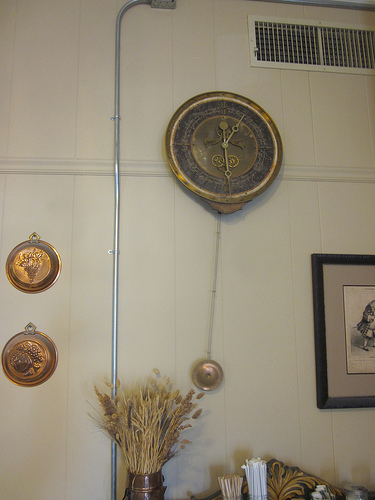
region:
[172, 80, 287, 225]
Clock on wall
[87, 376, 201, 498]
Cluster of wheat in container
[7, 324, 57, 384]
Bronze circle on wall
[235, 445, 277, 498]
White straws are clustered together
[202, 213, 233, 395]
Pendulum on clock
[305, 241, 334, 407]
Black border of picture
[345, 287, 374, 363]
Portrait of Alice in Wonderland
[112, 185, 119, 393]
Pole on wall is silver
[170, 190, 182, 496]
Cleft between two boards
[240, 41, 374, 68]
White vent in wall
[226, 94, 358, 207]
a clock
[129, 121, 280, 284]
a clock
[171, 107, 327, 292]
a clock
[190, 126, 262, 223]
a clock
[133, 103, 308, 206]
a clock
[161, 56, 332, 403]
a clock on the wall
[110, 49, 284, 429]
an old clock on the wall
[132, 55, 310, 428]
an antique clock on the wall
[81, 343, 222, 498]
a vase of plants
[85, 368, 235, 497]
plants in a vase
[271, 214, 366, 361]
a picture on the wall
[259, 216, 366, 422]
a framed picture on the wall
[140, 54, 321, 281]
a clock with gold arms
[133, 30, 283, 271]
a clock with fancy arms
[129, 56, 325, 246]
a clock with gold fancy arms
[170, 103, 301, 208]
antique gold clock on wall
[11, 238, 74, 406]
set of copper and gold pots on wall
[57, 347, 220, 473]
tan colored wheat plant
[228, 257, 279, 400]
white paneling on wall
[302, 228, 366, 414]
black framed art on wall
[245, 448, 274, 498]
a stack of straws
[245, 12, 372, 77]
white vent on near ceiling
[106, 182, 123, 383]
silver pole on wall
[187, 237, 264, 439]
gold bell with stick attatched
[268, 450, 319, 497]
gold and black designed sculpture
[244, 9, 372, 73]
the vent is high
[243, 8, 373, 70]
the vent is metal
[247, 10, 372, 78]
the vent is white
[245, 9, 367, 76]
the vent is in the wall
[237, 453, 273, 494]
the sraw wrappers are white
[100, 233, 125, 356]
the pipe is attached to the wall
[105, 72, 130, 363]
the pipe is thin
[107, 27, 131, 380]
the pipe is silver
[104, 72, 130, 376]
the pipe is metal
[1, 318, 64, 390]
the bowl is golden